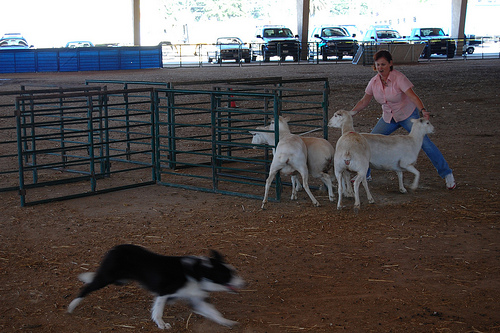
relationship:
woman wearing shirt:
[353, 46, 459, 186] [361, 71, 422, 123]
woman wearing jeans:
[353, 46, 459, 186] [367, 108, 455, 185]